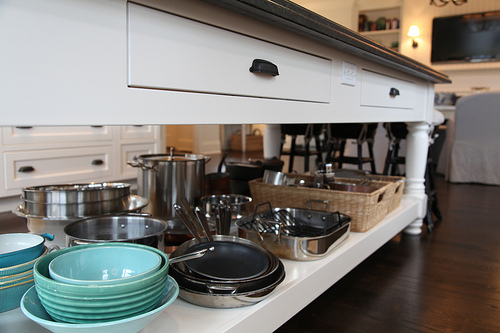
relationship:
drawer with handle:
[128, 4, 341, 105] [246, 54, 285, 81]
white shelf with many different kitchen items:
[3, 177, 410, 332] [0, 111, 401, 331]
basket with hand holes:
[248, 172, 394, 232] [368, 179, 402, 203]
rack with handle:
[239, 200, 342, 235] [249, 201, 274, 216]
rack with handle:
[239, 200, 342, 235] [321, 210, 341, 227]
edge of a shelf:
[213, 0, 452, 84] [350, 0, 400, 55]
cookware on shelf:
[125, 140, 214, 239] [2, 177, 428, 329]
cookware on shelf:
[9, 168, 151, 248] [2, 177, 428, 329]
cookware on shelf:
[60, 207, 172, 256] [2, 177, 428, 329]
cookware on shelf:
[25, 237, 176, 327] [2, 177, 428, 329]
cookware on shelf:
[232, 196, 355, 265] [2, 177, 428, 329]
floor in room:
[286, 171, 499, 332] [2, 4, 496, 326]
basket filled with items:
[257, 159, 409, 227] [261, 156, 376, 192]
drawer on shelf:
[128, 0, 332, 104] [3, 5, 423, 117]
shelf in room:
[3, 5, 423, 117] [2, 4, 496, 326]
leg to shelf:
[403, 122, 429, 235] [277, 0, 467, 92]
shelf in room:
[277, 0, 467, 92] [2, 4, 496, 326]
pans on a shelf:
[166, 231, 290, 325] [54, 93, 409, 304]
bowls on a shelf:
[22, 240, 182, 330] [133, 195, 432, 330]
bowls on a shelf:
[0, 226, 49, 311] [133, 195, 432, 330]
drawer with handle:
[361, 68, 418, 108] [388, 87, 401, 98]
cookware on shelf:
[126, 153, 212, 246] [1, 193, 426, 332]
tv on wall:
[427, 7, 497, 69] [293, 1, 498, 101]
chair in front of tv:
[450, 82, 499, 188] [432, 10, 497, 66]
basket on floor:
[229, 128, 264, 153] [2, 144, 499, 331]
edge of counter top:
[202, 0, 452, 84] [0, 0, 452, 331]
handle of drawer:
[246, 54, 285, 81] [128, 4, 341, 105]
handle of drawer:
[386, 85, 403, 100] [134, 2, 441, 114]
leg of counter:
[405, 120, 431, 235] [256, 4, 474, 85]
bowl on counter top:
[19, 275, 180, 331] [0, 0, 452, 333]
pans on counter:
[183, 204, 269, 281] [2, 2, 480, 327]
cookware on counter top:
[63, 213, 169, 249] [0, 0, 452, 333]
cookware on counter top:
[126, 153, 212, 246] [0, 0, 452, 333]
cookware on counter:
[234, 199, 354, 262] [1, 0, 468, 152]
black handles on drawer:
[16, 159, 108, 171] [0, 144, 109, 190]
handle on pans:
[191, 204, 215, 247] [183, 204, 269, 281]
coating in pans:
[191, 243, 262, 276] [183, 204, 269, 281]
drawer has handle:
[128, 4, 341, 105] [247, 56, 288, 83]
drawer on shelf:
[128, 4, 341, 105] [0, 0, 454, 130]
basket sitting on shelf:
[306, 169, 406, 211] [1, 193, 426, 332]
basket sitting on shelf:
[248, 172, 394, 232] [1, 193, 426, 332]